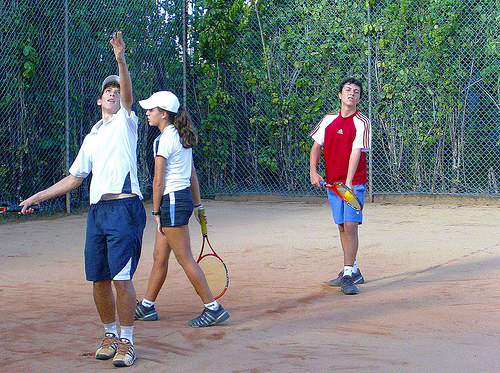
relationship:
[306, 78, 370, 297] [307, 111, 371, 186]
boy wearing shirt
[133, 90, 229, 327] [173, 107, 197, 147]
girl has ponytail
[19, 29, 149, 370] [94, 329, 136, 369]
boy wearing shoes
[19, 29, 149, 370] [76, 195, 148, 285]
boy wearing shorts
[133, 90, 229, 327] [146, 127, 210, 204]
girl wearing shirt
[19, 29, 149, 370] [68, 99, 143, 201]
boy wearing shirt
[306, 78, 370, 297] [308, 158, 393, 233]
boy wearing shorts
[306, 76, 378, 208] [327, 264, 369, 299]
boy wearing shoes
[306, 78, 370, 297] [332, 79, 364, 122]
boy has head